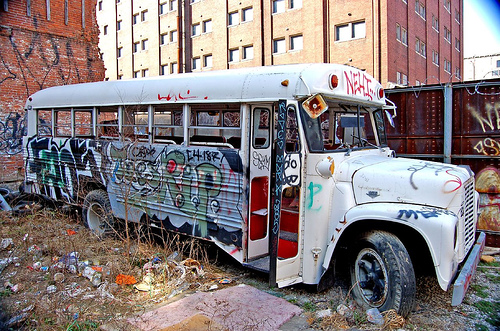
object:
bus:
[21, 63, 488, 320]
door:
[245, 105, 275, 263]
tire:
[342, 226, 417, 320]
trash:
[81, 266, 104, 287]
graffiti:
[0, 17, 96, 99]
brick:
[66, 28, 73, 32]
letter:
[343, 70, 354, 94]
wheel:
[336, 230, 417, 323]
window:
[188, 103, 242, 149]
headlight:
[315, 156, 335, 180]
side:
[19, 61, 321, 288]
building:
[96, 0, 465, 90]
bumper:
[449, 228, 489, 307]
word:
[106, 142, 163, 196]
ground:
[0, 196, 499, 330]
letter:
[186, 149, 194, 162]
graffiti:
[24, 133, 244, 254]